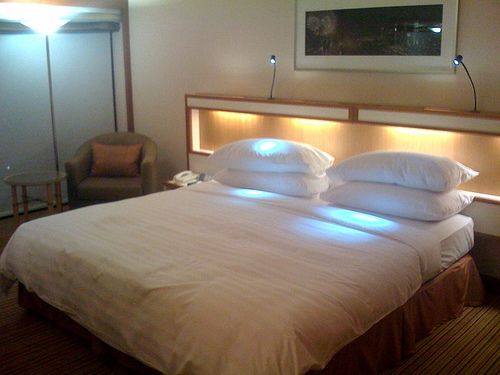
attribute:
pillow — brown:
[88, 140, 142, 177]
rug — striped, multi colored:
[426, 316, 491, 371]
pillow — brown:
[95, 148, 138, 173]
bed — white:
[7, 139, 424, 356]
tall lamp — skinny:
[2, 2, 93, 206]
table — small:
[4, 169, 68, 228]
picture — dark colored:
[289, 2, 470, 75]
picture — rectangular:
[293, 0, 462, 77]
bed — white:
[15, 118, 468, 373]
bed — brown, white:
[3, 106, 447, 328]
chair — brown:
[39, 117, 172, 196]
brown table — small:
[7, 171, 68, 186]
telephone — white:
[172, 169, 227, 199]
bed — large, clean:
[5, 137, 479, 372]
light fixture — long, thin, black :
[263, 51, 280, 100]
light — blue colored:
[266, 55, 277, 70]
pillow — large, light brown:
[87, 137, 152, 185]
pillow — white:
[211, 168, 330, 200]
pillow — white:
[200, 137, 334, 177]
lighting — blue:
[253, 136, 283, 154]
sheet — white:
[286, 199, 329, 231]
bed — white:
[43, 208, 495, 360]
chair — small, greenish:
[66, 131, 158, 209]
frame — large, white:
[293, 3, 460, 71]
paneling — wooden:
[186, 91, 497, 235]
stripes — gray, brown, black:
[435, 317, 485, 371]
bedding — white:
[1, 137, 478, 373]